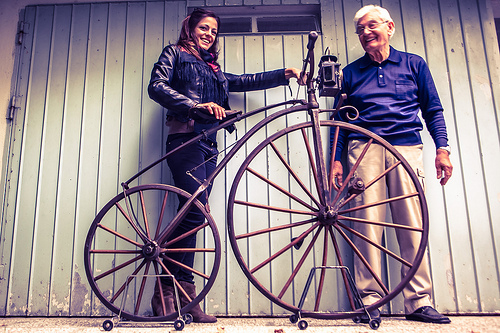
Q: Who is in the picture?
A: A man and a woman.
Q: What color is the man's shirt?
A: Blue.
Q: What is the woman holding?
A: A bike.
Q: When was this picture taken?
A: Daytime.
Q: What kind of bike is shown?
A: An antique.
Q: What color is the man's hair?
A: Grey.